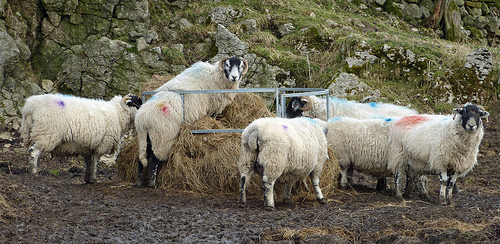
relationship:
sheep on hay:
[120, 50, 246, 168] [191, 159, 229, 188]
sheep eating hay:
[244, 92, 335, 206] [191, 159, 229, 188]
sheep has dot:
[12, 97, 133, 182] [52, 98, 68, 112]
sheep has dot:
[120, 50, 246, 168] [156, 103, 169, 123]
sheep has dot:
[397, 99, 499, 176] [399, 113, 417, 131]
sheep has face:
[120, 50, 246, 168] [215, 49, 245, 93]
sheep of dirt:
[12, 97, 133, 182] [66, 197, 96, 218]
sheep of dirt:
[120, 50, 246, 168] [66, 197, 96, 218]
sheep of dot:
[244, 92, 335, 206] [52, 98, 68, 112]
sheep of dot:
[397, 99, 499, 176] [52, 98, 68, 112]